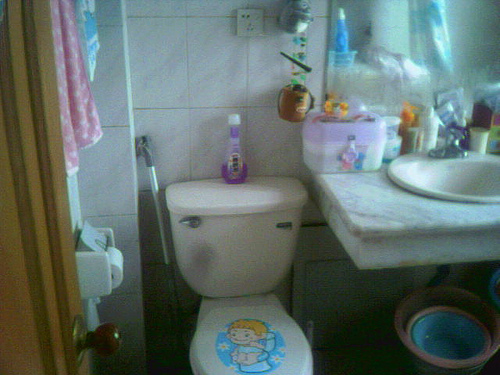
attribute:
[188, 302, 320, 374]
toilet lid — white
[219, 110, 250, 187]
cleaning liquid — purple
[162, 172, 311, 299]
toilet tank — white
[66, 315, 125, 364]
handle — gold, brown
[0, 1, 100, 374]
door — wooden, brown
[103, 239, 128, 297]
toilet paper — white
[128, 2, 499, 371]
wall — tiled, white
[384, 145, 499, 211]
sink — white, porcelain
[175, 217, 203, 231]
handle — silver, metal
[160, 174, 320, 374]
toilet — white, ceramic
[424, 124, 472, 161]
faucet — silver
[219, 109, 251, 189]
bottle — plastic, purple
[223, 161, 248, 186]
liquid — purple, blue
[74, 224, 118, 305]
holder — white, plastic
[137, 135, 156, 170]
handle — grey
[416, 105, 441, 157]
bottle — white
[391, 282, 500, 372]
pot — brown, blue, tan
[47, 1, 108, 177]
towel — pink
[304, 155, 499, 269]
counter — white, marble